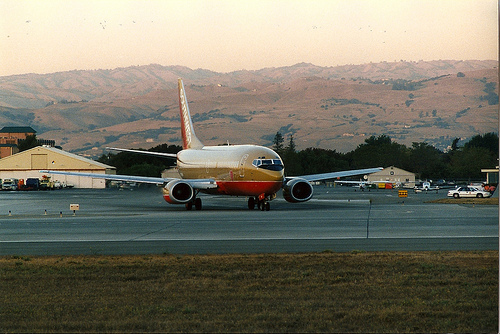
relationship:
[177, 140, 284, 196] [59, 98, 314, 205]
fuselage of plane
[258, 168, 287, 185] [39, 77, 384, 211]
nose on airplane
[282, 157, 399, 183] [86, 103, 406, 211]
wing on plane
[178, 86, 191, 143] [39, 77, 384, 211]
airline name that operates airplane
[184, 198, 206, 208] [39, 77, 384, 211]
black wheels on airplane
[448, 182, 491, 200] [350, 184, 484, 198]
car parked in lot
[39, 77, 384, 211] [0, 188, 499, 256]
airplane parked on cement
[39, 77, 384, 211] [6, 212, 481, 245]
airplane sitting on runway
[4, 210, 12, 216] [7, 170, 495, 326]
object attached to ground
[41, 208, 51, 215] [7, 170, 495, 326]
object attached to ground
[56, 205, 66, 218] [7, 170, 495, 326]
object attached to ground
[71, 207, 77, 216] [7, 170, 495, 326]
object attached to ground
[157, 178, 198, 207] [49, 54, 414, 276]
engine on plane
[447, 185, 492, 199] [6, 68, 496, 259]
car parked at airport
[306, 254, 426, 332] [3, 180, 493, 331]
grass on ground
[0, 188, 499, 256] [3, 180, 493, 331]
cement on ground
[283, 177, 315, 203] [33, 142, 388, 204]
engine on plane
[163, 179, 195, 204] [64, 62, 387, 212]
engine on plane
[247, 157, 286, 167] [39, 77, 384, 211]
windshield on airplane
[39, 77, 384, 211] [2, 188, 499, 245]
airplane on runway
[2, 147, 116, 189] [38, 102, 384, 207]
building behind plane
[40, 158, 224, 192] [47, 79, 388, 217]
wing on jet airplane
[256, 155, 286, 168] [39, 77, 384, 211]
cockpit area on airplane